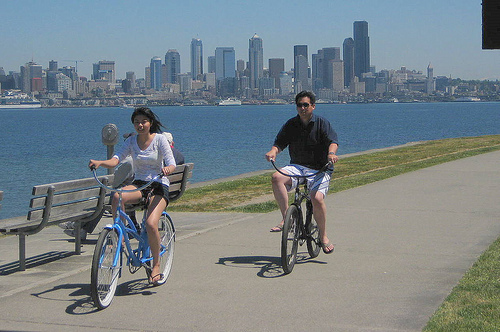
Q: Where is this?
A: This is at the sidewalk.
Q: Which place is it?
A: It is a sidewalk.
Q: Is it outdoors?
A: Yes, it is outdoors.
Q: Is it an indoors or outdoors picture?
A: It is outdoors.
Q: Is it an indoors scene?
A: No, it is outdoors.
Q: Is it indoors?
A: No, it is outdoors.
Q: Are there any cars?
A: No, there are no cars.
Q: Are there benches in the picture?
A: Yes, there is a bench.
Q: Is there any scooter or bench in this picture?
A: Yes, there is a bench.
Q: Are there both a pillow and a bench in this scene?
A: No, there is a bench but no pillows.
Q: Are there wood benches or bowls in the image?
A: Yes, there is a wood bench.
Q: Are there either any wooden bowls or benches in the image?
A: Yes, there is a wood bench.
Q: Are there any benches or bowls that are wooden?
A: Yes, the bench is wooden.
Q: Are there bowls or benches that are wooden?
A: Yes, the bench is wooden.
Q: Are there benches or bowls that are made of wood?
A: Yes, the bench is made of wood.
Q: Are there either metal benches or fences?
A: Yes, there is a metal bench.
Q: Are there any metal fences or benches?
A: Yes, there is a metal bench.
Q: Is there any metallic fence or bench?
A: Yes, there is a metal bench.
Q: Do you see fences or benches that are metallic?
A: Yes, the bench is metallic.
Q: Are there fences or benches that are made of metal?
A: Yes, the bench is made of metal.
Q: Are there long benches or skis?
A: Yes, there is a long bench.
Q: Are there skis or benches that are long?
A: Yes, the bench is long.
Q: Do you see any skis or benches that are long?
A: Yes, the bench is long.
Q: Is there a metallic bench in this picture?
A: Yes, there is a metal bench.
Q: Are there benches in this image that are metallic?
A: Yes, there is a bench that is metallic.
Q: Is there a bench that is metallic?
A: Yes, there is a bench that is metallic.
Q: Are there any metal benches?
A: Yes, there is a bench that is made of metal.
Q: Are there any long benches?
A: Yes, there is a long bench.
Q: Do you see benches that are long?
A: Yes, there is a bench that is long.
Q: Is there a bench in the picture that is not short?
A: Yes, there is a long bench.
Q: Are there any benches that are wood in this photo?
A: Yes, there is a wood bench.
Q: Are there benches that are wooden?
A: Yes, there is a bench that is wooden.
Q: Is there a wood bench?
A: Yes, there is a bench that is made of wood.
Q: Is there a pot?
A: No, there are no pots.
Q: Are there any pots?
A: No, there are no pots.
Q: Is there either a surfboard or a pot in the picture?
A: No, there are no pots or surfboards.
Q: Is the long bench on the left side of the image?
A: Yes, the bench is on the left of the image.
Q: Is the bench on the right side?
A: No, the bench is on the left of the image.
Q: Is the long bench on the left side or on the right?
A: The bench is on the left of the image.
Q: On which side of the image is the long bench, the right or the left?
A: The bench is on the left of the image.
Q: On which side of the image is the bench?
A: The bench is on the left of the image.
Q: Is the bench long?
A: Yes, the bench is long.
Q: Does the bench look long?
A: Yes, the bench is long.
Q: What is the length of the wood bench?
A: The bench is long.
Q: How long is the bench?
A: The bench is long.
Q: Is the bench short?
A: No, the bench is long.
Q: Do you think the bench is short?
A: No, the bench is long.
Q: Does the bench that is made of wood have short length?
A: No, the bench is long.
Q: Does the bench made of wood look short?
A: No, the bench is long.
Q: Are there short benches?
A: No, there is a bench but it is long.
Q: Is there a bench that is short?
A: No, there is a bench but it is long.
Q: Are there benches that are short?
A: No, there is a bench but it is long.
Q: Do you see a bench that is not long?
A: No, there is a bench but it is long.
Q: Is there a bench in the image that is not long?
A: No, there is a bench but it is long.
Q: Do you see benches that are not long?
A: No, there is a bench but it is long.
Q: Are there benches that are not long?
A: No, there is a bench but it is long.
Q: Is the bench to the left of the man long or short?
A: The bench is long.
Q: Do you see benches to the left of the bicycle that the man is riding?
A: Yes, there is a bench to the left of the bicycle.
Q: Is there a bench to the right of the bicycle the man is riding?
A: No, the bench is to the left of the bicycle.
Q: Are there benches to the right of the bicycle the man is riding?
A: No, the bench is to the left of the bicycle.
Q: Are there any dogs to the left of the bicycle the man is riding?
A: No, there is a bench to the left of the bicycle.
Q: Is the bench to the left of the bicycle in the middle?
A: Yes, the bench is to the left of the bicycle.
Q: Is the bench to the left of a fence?
A: No, the bench is to the left of the bicycle.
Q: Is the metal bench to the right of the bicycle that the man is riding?
A: No, the bench is to the left of the bicycle.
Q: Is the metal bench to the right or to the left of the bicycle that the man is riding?
A: The bench is to the left of the bicycle.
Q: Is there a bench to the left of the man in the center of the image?
A: Yes, there is a bench to the left of the man.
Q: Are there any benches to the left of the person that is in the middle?
A: Yes, there is a bench to the left of the man.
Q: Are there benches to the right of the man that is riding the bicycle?
A: No, the bench is to the left of the man.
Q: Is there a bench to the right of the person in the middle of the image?
A: No, the bench is to the left of the man.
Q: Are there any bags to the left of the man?
A: No, there is a bench to the left of the man.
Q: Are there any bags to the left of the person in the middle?
A: No, there is a bench to the left of the man.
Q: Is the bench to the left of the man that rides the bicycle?
A: Yes, the bench is to the left of the man.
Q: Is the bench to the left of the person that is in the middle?
A: Yes, the bench is to the left of the man.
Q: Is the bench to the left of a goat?
A: No, the bench is to the left of the man.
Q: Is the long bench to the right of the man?
A: No, the bench is to the left of the man.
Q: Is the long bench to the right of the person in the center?
A: No, the bench is to the left of the man.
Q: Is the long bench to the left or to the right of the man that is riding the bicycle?
A: The bench is to the left of the man.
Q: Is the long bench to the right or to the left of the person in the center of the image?
A: The bench is to the left of the man.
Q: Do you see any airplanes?
A: No, there are no airplanes.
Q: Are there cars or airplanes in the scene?
A: No, there are no airplanes or cars.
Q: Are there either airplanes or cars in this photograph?
A: No, there are no airplanes or cars.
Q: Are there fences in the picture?
A: No, there are no fences.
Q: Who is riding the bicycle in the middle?
A: The man is riding the bicycle.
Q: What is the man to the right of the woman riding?
A: The man is riding the bicycle.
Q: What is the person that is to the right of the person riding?
A: The man is riding the bicycle.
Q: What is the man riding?
A: The man is riding the bicycle.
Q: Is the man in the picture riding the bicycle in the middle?
A: Yes, the man is riding the bicycle.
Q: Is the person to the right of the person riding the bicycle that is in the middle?
A: Yes, the man is riding the bicycle.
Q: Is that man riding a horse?
A: No, the man is riding the bicycle.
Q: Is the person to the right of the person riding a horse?
A: No, the man is riding the bicycle.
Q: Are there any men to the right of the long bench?
A: Yes, there is a man to the right of the bench.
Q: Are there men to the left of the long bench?
A: No, the man is to the right of the bench.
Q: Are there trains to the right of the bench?
A: No, there is a man to the right of the bench.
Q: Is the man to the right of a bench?
A: Yes, the man is to the right of a bench.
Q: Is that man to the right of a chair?
A: No, the man is to the right of a bench.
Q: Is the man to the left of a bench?
A: No, the man is to the right of a bench.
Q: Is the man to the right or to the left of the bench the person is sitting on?
A: The man is to the right of the bench.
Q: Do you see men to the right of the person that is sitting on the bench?
A: Yes, there is a man to the right of the person.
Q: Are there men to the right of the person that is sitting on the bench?
A: Yes, there is a man to the right of the person.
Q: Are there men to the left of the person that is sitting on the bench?
A: No, the man is to the right of the person.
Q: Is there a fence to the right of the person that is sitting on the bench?
A: No, there is a man to the right of the person.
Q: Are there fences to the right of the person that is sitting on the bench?
A: No, there is a man to the right of the person.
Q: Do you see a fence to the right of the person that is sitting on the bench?
A: No, there is a man to the right of the person.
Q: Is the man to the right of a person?
A: Yes, the man is to the right of a person.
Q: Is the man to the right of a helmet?
A: No, the man is to the right of a person.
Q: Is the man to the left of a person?
A: No, the man is to the right of a person.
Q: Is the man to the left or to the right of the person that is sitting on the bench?
A: The man is to the right of the person.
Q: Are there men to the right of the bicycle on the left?
A: Yes, there is a man to the right of the bicycle.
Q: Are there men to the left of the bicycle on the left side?
A: No, the man is to the right of the bicycle.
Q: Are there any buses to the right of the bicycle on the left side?
A: No, there is a man to the right of the bicycle.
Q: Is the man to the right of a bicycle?
A: Yes, the man is to the right of a bicycle.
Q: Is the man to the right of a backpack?
A: No, the man is to the right of a bicycle.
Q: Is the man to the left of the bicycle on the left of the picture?
A: No, the man is to the right of the bicycle.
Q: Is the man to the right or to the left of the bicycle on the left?
A: The man is to the right of the bicycle.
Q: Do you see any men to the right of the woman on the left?
A: Yes, there is a man to the right of the woman.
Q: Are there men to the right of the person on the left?
A: Yes, there is a man to the right of the woman.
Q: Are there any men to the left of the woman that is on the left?
A: No, the man is to the right of the woman.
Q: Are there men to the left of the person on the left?
A: No, the man is to the right of the woman.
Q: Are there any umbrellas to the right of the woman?
A: No, there is a man to the right of the woman.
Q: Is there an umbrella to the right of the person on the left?
A: No, there is a man to the right of the woman.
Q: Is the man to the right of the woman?
A: Yes, the man is to the right of the woman.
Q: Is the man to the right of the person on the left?
A: Yes, the man is to the right of the woman.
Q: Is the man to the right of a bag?
A: No, the man is to the right of the woman.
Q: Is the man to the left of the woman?
A: No, the man is to the right of the woman.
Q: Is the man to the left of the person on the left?
A: No, the man is to the right of the woman.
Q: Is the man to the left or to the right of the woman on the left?
A: The man is to the right of the woman.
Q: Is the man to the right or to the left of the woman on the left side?
A: The man is to the right of the woman.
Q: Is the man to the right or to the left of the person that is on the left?
A: The man is to the right of the woman.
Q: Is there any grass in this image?
A: Yes, there is grass.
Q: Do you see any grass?
A: Yes, there is grass.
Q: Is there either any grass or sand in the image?
A: Yes, there is grass.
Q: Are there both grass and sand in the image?
A: No, there is grass but no sand.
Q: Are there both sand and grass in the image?
A: No, there is grass but no sand.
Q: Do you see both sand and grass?
A: No, there is grass but no sand.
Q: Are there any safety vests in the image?
A: No, there are no safety vests.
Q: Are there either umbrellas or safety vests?
A: No, there are no safety vests or umbrellas.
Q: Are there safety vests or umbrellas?
A: No, there are no safety vests or umbrellas.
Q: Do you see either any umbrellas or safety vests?
A: No, there are no safety vests or umbrellas.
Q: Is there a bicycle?
A: Yes, there is a bicycle.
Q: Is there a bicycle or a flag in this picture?
A: Yes, there is a bicycle.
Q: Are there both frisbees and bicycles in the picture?
A: No, there is a bicycle but no frisbees.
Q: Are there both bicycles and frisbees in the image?
A: No, there is a bicycle but no frisbees.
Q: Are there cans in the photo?
A: No, there are no cans.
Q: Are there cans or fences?
A: No, there are no cans or fences.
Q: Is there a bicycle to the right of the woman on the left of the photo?
A: Yes, there is a bicycle to the right of the woman.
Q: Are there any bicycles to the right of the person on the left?
A: Yes, there is a bicycle to the right of the woman.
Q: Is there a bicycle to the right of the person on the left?
A: Yes, there is a bicycle to the right of the woman.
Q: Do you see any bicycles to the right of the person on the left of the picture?
A: Yes, there is a bicycle to the right of the woman.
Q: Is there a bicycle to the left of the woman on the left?
A: No, the bicycle is to the right of the woman.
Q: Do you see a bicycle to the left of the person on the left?
A: No, the bicycle is to the right of the woman.